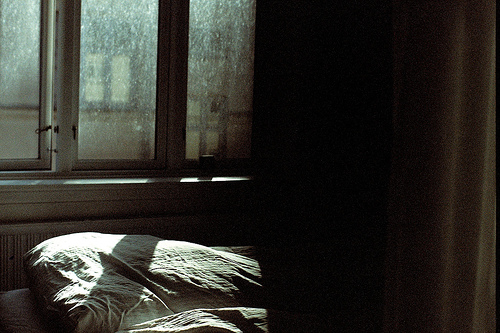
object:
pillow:
[71, 228, 263, 310]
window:
[85, 43, 149, 121]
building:
[3, 1, 245, 118]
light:
[56, 232, 100, 281]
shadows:
[109, 227, 151, 305]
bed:
[4, 220, 257, 333]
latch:
[34, 120, 50, 138]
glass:
[78, 1, 154, 163]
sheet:
[187, 231, 252, 282]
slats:
[0, 234, 24, 285]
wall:
[260, 0, 381, 316]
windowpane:
[191, 1, 248, 161]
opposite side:
[260, 17, 354, 148]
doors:
[76, 38, 141, 114]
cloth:
[59, 249, 147, 282]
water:
[202, 157, 215, 174]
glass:
[198, 141, 216, 188]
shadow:
[164, 180, 228, 201]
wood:
[55, 116, 74, 177]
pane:
[4, 5, 69, 177]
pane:
[83, 6, 162, 160]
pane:
[178, 5, 251, 171]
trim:
[49, 9, 80, 171]